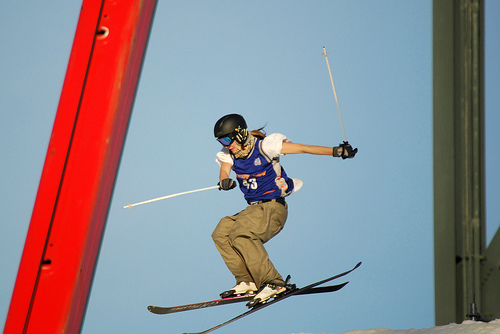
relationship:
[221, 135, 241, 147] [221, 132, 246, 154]
goggles on face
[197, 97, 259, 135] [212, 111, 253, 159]
helmet on head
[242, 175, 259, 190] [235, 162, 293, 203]
numbers on stomach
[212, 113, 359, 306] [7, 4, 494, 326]
person in air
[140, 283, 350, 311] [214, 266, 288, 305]
skis attached to feet